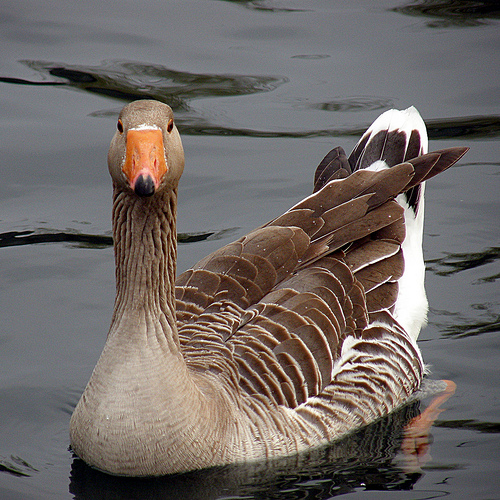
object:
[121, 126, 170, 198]
beak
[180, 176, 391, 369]
feather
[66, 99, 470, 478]
duck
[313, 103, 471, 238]
tail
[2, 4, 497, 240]
water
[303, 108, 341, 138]
bad sentence